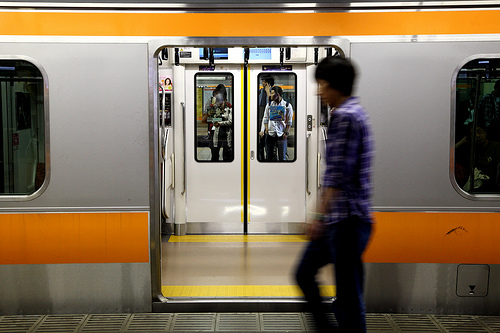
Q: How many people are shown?
A: 4.